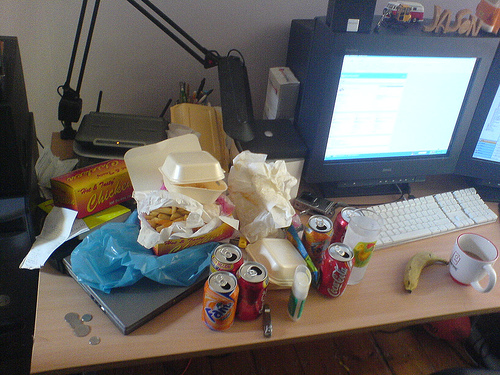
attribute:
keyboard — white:
[343, 196, 492, 234]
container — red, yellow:
[49, 158, 132, 219]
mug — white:
[447, 234, 497, 294]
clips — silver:
[245, 284, 300, 366]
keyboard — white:
[336, 190, 498, 251]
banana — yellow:
[397, 237, 464, 318]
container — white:
[133, 140, 232, 202]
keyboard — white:
[344, 189, 498, 242]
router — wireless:
[73, 89, 176, 163]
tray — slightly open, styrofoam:
[159, 151, 231, 206]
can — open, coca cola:
[318, 244, 347, 299]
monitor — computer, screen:
[273, 10, 498, 254]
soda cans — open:
[303, 216, 360, 299]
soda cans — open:
[200, 245, 270, 325]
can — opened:
[210, 243, 242, 275]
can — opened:
[318, 243, 354, 298]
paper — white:
[129, 184, 205, 247]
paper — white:
[131, 189, 214, 248]